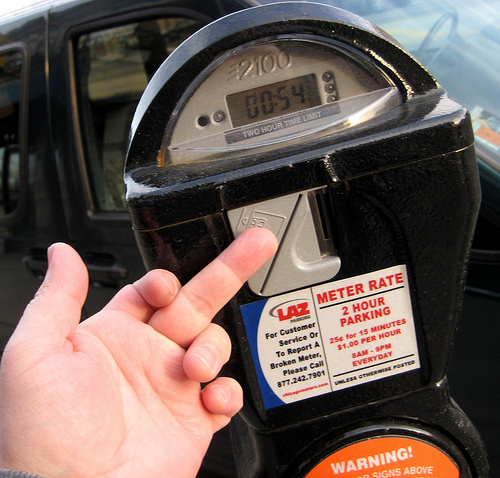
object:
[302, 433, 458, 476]
sticker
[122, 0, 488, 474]
meter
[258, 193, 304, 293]
coin slot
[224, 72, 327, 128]
time display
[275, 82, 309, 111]
54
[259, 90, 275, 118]
zeroes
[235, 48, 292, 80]
number 2100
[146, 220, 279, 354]
middle finger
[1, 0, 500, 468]
vehicle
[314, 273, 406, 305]
meter rate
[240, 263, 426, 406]
sticker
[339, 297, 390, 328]
2 hour parking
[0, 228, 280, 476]
hand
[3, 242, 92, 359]
thumb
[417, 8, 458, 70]
steering wheel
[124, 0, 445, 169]
top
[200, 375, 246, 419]
pinkie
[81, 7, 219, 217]
window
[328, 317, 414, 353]
rates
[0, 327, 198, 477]
palm